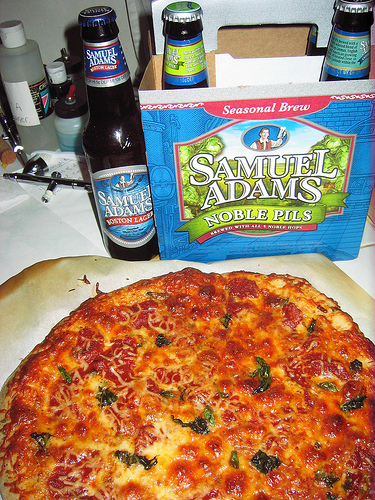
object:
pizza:
[0, 267, 375, 500]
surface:
[89, 313, 324, 491]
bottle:
[75, 5, 162, 262]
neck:
[80, 38, 137, 104]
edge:
[108, 260, 321, 295]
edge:
[132, 87, 169, 261]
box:
[136, 0, 374, 261]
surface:
[147, 97, 370, 262]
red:
[194, 90, 334, 123]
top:
[75, 0, 127, 41]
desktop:
[4, 205, 86, 250]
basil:
[183, 399, 222, 438]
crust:
[24, 323, 82, 384]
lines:
[106, 333, 141, 383]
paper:
[60, 192, 85, 214]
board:
[34, 266, 74, 305]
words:
[180, 147, 340, 239]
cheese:
[150, 340, 316, 445]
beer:
[147, 1, 217, 91]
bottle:
[45, 58, 75, 103]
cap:
[0, 12, 28, 52]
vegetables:
[250, 340, 365, 420]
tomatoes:
[139, 324, 204, 379]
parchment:
[0, 254, 374, 335]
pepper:
[42, 471, 72, 494]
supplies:
[0, 9, 87, 161]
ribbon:
[173, 204, 327, 245]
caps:
[74, 2, 118, 36]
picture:
[172, 110, 355, 245]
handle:
[207, 10, 323, 71]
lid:
[0, 21, 28, 52]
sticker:
[85, 161, 162, 251]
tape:
[36, 185, 61, 209]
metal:
[0, 155, 92, 211]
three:
[75, 0, 375, 95]